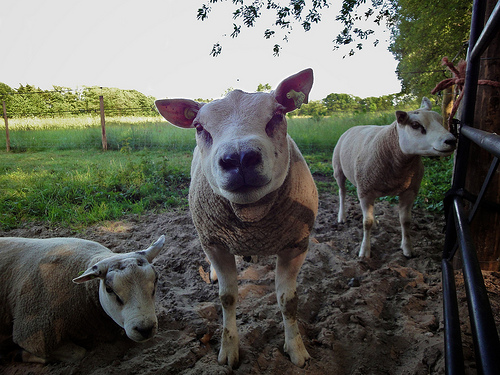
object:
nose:
[134, 322, 156, 339]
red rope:
[431, 56, 500, 138]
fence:
[1, 91, 181, 152]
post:
[99, 95, 107, 153]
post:
[0, 100, 12, 153]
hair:
[112, 254, 149, 271]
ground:
[374, 290, 420, 338]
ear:
[72, 263, 106, 285]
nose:
[217, 150, 263, 172]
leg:
[273, 261, 300, 338]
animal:
[328, 101, 456, 260]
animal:
[154, 67, 314, 368]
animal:
[0, 235, 165, 375]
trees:
[0, 0, 500, 129]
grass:
[53, 115, 427, 130]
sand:
[3, 182, 498, 372]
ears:
[391, 108, 411, 129]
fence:
[439, 0, 500, 370]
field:
[0, 113, 432, 375]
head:
[73, 235, 183, 342]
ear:
[154, 98, 201, 127]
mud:
[277, 290, 298, 322]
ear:
[267, 68, 314, 117]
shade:
[0, 114, 500, 375]